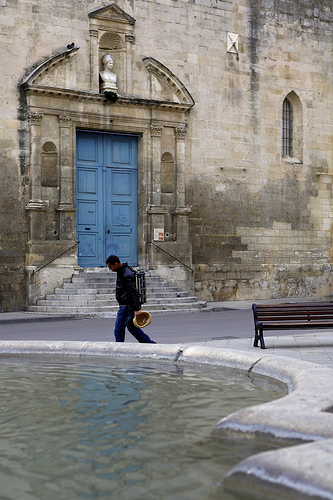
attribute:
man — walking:
[104, 257, 159, 345]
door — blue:
[75, 127, 137, 268]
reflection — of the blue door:
[74, 366, 155, 489]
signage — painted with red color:
[151, 225, 168, 242]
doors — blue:
[70, 129, 134, 252]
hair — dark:
[85, 253, 123, 285]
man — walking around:
[104, 252, 154, 345]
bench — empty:
[243, 286, 321, 325]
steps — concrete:
[29, 263, 205, 316]